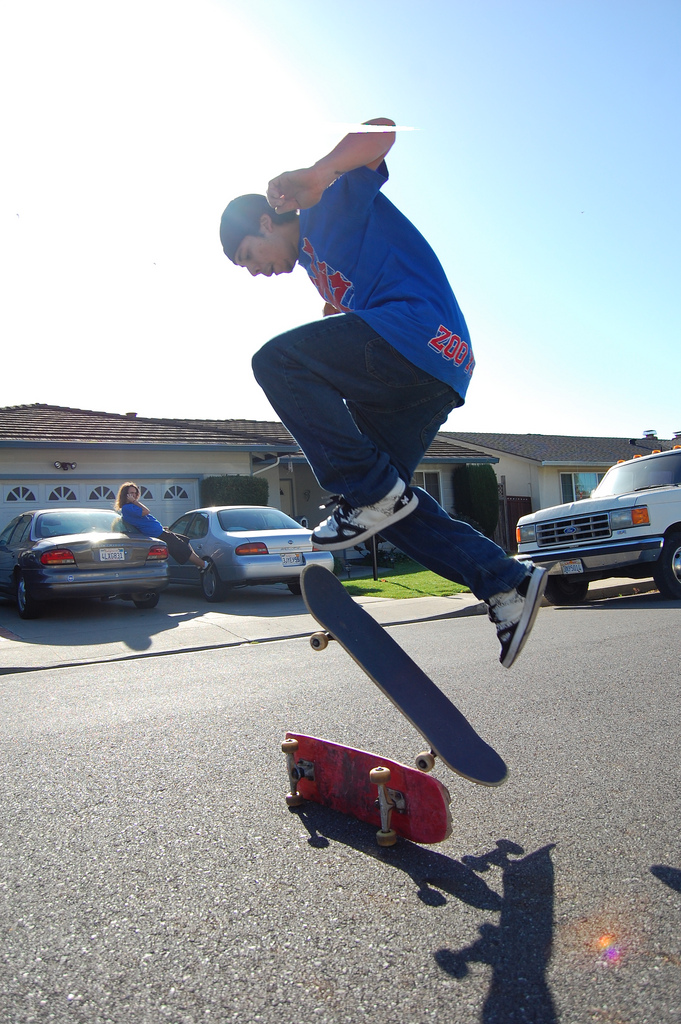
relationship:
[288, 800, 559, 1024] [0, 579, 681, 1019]
shadow on street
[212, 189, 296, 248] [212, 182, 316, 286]
hat on h head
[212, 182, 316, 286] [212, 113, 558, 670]
head of boy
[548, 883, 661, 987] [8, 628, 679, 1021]
spray paiint on street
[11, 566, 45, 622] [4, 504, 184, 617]
wheel on vehicle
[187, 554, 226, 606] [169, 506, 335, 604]
wheel on car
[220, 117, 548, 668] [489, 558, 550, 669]
boy wearing shoe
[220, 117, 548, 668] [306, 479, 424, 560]
boy wearing shoe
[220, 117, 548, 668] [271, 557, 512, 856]
boy has skateboard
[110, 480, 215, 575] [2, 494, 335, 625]
girl leaning on cars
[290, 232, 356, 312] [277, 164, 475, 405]
writing on guy's shirt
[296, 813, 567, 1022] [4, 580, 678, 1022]
shadow on road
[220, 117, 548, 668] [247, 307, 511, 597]
boy wearing jeans